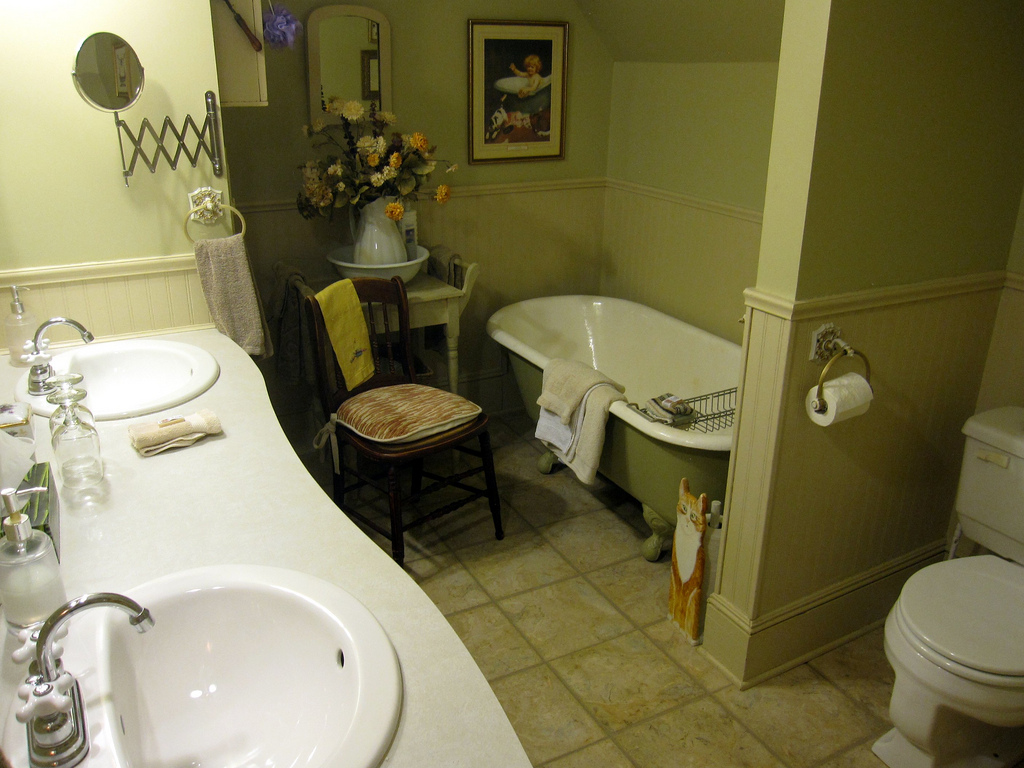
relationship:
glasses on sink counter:
[35, 363, 116, 526] [27, 314, 531, 762]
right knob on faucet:
[18, 610, 68, 671] [12, 592, 153, 765]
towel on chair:
[314, 278, 375, 391] [284, 262, 513, 569]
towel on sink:
[122, 404, 231, 465] [17, 329, 229, 436]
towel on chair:
[310, 271, 380, 397] [310, 273, 516, 589]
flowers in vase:
[289, 76, 464, 232] [340, 191, 420, 272]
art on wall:
[457, 7, 572, 170] [209, 1, 616, 421]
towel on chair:
[310, 271, 380, 397] [295, 268, 516, 577]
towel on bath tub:
[531, 353, 625, 481] [478, 290, 747, 561]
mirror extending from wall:
[71, 32, 223, 187] [0, 7, 238, 338]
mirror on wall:
[71, 29, 232, 177] [0, 7, 238, 338]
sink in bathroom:
[17, 564, 400, 765] [7, 9, 1021, 764]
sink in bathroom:
[19, 336, 218, 421] [7, 9, 1021, 764]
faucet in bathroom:
[12, 592, 153, 765] [7, 9, 1021, 764]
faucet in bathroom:
[17, 316, 95, 394] [7, 9, 1021, 764]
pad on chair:
[318, 376, 481, 446] [295, 268, 516, 577]